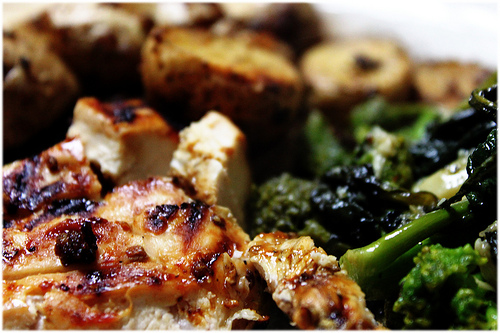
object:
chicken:
[66, 97, 251, 230]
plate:
[0, 0, 497, 69]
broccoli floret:
[250, 171, 332, 244]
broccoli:
[393, 237, 497, 329]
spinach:
[307, 82, 498, 290]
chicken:
[3, 135, 251, 331]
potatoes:
[2, 2, 495, 150]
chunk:
[66, 97, 181, 198]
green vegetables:
[249, 69, 497, 330]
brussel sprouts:
[308, 160, 413, 250]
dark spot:
[53, 217, 107, 299]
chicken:
[3, 97, 386, 330]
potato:
[298, 34, 415, 110]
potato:
[138, 26, 305, 146]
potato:
[3, 2, 161, 131]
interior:
[119, 305, 194, 331]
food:
[3, 2, 498, 331]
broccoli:
[339, 197, 497, 330]